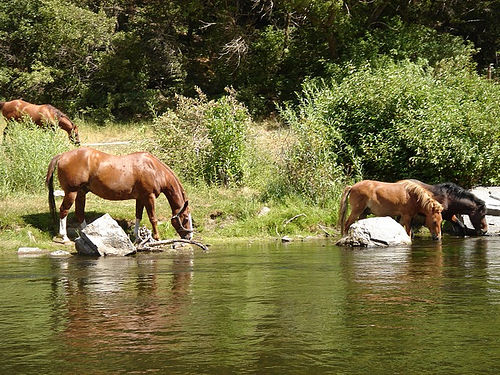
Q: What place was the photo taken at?
A: It was taken at the forest.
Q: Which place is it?
A: It is a forest.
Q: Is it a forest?
A: Yes, it is a forest.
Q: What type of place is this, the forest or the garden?
A: It is the forest.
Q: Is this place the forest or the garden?
A: It is the forest.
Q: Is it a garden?
A: No, it is a forest.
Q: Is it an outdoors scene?
A: Yes, it is outdoors.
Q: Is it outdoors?
A: Yes, it is outdoors.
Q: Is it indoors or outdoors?
A: It is outdoors.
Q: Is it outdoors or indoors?
A: It is outdoors.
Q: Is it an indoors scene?
A: No, it is outdoors.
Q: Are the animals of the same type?
A: Yes, all the animals are horses.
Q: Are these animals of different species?
A: No, all the animals are horses.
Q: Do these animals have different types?
A: No, all the animals are horses.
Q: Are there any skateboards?
A: No, there are no skateboards.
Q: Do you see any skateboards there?
A: No, there are no skateboards.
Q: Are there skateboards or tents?
A: No, there are no skateboards or tents.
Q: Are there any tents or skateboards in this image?
A: No, there are no skateboards or tents.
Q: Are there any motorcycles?
A: No, there are no motorcycles.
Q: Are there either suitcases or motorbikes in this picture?
A: No, there are no motorbikes or suitcases.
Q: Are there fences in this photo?
A: No, there are no fences.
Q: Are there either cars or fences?
A: No, there are no fences or cars.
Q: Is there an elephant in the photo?
A: No, there are no elephants.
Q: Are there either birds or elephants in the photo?
A: No, there are no elephants or birds.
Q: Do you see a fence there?
A: No, there are no fences.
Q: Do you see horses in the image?
A: Yes, there is a horse.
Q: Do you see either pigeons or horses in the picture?
A: Yes, there is a horse.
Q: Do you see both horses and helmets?
A: No, there is a horse but no helmets.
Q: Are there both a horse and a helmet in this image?
A: No, there is a horse but no helmets.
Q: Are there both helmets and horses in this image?
A: No, there is a horse but no helmets.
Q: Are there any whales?
A: No, there are no whales.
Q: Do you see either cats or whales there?
A: No, there are no whales or cats.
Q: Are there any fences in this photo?
A: No, there are no fences.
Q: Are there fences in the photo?
A: No, there are no fences.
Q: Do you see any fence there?
A: No, there are no fences.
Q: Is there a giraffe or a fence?
A: No, there are no fences or giraffes.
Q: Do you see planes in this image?
A: No, there are no planes.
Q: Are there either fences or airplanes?
A: No, there are no airplanes or fences.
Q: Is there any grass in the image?
A: Yes, there is grass.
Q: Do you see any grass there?
A: Yes, there is grass.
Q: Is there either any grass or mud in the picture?
A: Yes, there is grass.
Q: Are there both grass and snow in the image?
A: No, there is grass but no snow.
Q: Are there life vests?
A: No, there are no life vests.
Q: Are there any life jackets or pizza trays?
A: No, there are no life jackets or pizza trays.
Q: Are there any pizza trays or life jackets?
A: No, there are no life jackets or pizza trays.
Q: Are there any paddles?
A: No, there are no paddles.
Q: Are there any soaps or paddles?
A: No, there are no paddles or soaps.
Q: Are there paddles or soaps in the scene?
A: No, there are no paddles or soaps.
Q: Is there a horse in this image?
A: Yes, there is a horse.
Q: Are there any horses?
A: Yes, there is a horse.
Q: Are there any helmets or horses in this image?
A: Yes, there is a horse.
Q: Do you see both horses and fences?
A: No, there is a horse but no fences.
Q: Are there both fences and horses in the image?
A: No, there is a horse but no fences.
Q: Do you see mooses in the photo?
A: No, there are no mooses.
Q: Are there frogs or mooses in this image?
A: No, there are no mooses or frogs.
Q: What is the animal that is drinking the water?
A: The animal is a horse.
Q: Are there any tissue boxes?
A: No, there are no tissue boxes.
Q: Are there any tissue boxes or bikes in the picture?
A: No, there are no tissue boxes or bikes.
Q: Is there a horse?
A: Yes, there is a horse.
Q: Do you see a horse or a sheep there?
A: Yes, there is a horse.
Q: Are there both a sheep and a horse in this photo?
A: No, there is a horse but no sheep.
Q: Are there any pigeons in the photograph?
A: No, there are no pigeons.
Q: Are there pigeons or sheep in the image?
A: No, there are no pigeons or sheep.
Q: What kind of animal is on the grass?
A: The animal is a horse.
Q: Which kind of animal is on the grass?
A: The animal is a horse.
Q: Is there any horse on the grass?
A: Yes, there is a horse on the grass.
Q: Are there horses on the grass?
A: Yes, there is a horse on the grass.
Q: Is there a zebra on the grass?
A: No, there is a horse on the grass.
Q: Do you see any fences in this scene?
A: No, there are no fences.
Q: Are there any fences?
A: No, there are no fences.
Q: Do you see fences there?
A: No, there are no fences.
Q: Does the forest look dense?
A: Yes, the forest is dense.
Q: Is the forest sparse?
A: No, the forest is dense.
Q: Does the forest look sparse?
A: No, the forest is dense.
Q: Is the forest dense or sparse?
A: The forest is dense.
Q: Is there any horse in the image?
A: Yes, there is a horse.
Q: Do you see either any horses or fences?
A: Yes, there is a horse.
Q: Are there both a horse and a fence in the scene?
A: No, there is a horse but no fences.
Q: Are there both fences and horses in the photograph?
A: No, there is a horse but no fences.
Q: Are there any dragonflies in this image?
A: No, there are no dragonflies.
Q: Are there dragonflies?
A: No, there are no dragonflies.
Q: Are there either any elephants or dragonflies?
A: No, there are no dragonflies or elephants.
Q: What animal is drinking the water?
A: The horse is drinking the water.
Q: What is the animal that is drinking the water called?
A: The animal is a horse.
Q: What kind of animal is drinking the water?
A: The animal is a horse.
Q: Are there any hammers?
A: No, there are no hammers.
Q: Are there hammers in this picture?
A: No, there are no hammers.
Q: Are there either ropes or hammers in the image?
A: No, there are no hammers or ropes.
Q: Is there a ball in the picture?
A: No, there are no balls.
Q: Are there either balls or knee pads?
A: No, there are no balls or knee pads.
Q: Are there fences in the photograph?
A: No, there are no fences.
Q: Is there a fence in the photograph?
A: No, there are no fences.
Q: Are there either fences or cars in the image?
A: No, there are no fences or cars.